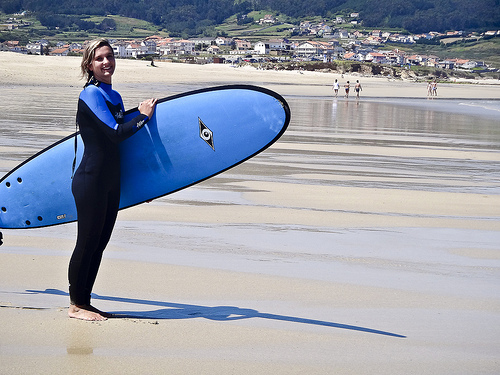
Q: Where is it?
A: This is at the beach.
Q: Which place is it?
A: It is a beach.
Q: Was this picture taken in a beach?
A: Yes, it was taken in a beach.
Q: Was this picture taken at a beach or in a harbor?
A: It was taken at a beach.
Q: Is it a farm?
A: No, it is a beach.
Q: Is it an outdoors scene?
A: Yes, it is outdoors.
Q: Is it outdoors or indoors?
A: It is outdoors.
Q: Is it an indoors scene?
A: No, it is outdoors.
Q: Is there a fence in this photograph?
A: No, there are no fences.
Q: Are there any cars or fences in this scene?
A: No, there are no fences or cars.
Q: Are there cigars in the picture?
A: No, there are no cigars.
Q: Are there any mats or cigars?
A: No, there are no cigars or mats.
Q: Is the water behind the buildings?
A: Yes, the water is behind the buildings.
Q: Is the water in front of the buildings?
A: No, the water is behind the buildings.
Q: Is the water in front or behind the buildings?
A: The water is behind the buildings.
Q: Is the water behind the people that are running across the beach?
A: Yes, the water is behind the people.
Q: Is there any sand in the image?
A: Yes, there is sand.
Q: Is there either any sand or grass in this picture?
A: Yes, there is sand.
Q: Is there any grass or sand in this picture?
A: Yes, there is sand.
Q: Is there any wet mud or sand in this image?
A: Yes, there is wet sand.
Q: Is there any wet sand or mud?
A: Yes, there is wet sand.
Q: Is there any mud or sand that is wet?
A: Yes, the sand is wet.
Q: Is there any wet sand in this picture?
A: Yes, there is wet sand.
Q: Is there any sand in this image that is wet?
A: Yes, there is sand that is wet.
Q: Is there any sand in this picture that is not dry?
A: Yes, there is wet sand.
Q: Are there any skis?
A: No, there are no skis.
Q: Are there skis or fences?
A: No, there are no skis or fences.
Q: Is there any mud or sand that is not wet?
A: No, there is sand but it is wet.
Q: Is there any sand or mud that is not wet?
A: No, there is sand but it is wet.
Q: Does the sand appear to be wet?
A: Yes, the sand is wet.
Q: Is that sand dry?
A: No, the sand is wet.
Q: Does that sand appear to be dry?
A: No, the sand is wet.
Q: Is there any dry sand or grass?
A: No, there is sand but it is wet.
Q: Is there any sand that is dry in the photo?
A: No, there is sand but it is wet.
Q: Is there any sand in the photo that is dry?
A: No, there is sand but it is wet.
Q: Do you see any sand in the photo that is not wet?
A: No, there is sand but it is wet.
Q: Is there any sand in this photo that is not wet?
A: No, there is sand but it is wet.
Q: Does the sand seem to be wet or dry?
A: The sand is wet.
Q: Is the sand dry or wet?
A: The sand is wet.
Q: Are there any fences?
A: No, there are no fences.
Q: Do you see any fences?
A: No, there are no fences.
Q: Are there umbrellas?
A: No, there are no umbrellas.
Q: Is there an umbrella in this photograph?
A: No, there are no umbrellas.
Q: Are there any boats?
A: No, there are no boats.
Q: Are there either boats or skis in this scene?
A: No, there are no boats or skis.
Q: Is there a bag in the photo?
A: No, there are no bags.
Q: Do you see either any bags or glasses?
A: No, there are no bags or glasses.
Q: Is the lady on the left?
A: Yes, the lady is on the left of the image.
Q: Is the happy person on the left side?
A: Yes, the lady is on the left of the image.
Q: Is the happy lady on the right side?
A: No, the lady is on the left of the image.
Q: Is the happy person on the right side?
A: No, the lady is on the left of the image.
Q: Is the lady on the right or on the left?
A: The lady is on the left of the image.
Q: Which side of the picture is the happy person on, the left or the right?
A: The lady is on the left of the image.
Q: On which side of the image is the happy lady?
A: The lady is on the left of the image.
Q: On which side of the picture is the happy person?
A: The lady is on the left of the image.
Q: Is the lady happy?
A: Yes, the lady is happy.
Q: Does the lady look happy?
A: Yes, the lady is happy.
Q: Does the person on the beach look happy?
A: Yes, the lady is happy.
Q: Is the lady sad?
A: No, the lady is happy.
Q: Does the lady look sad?
A: No, the lady is happy.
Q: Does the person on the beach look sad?
A: No, the lady is happy.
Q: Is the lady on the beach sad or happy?
A: The lady is happy.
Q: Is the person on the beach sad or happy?
A: The lady is happy.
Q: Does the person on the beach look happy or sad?
A: The lady is happy.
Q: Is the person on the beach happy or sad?
A: The lady is happy.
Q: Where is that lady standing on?
A: The lady is standing on the beach.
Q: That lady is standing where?
A: The lady is standing on the beach.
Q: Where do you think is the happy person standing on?
A: The lady is standing on the beach.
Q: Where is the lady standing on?
A: The lady is standing on the beach.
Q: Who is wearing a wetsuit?
A: The lady is wearing a wetsuit.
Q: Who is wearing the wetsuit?
A: The lady is wearing a wetsuit.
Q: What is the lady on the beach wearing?
A: The lady is wearing a wetsuit.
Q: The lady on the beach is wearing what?
A: The lady is wearing a wetsuit.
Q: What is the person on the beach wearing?
A: The lady is wearing a wetsuit.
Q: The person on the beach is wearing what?
A: The lady is wearing a wetsuit.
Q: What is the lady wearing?
A: The lady is wearing a wetsuit.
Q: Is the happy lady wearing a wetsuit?
A: Yes, the lady is wearing a wetsuit.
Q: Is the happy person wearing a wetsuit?
A: Yes, the lady is wearing a wetsuit.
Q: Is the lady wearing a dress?
A: No, the lady is wearing a wetsuit.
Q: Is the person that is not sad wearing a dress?
A: No, the lady is wearing a wetsuit.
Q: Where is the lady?
A: The lady is on the beach.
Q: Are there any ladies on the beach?
A: Yes, there is a lady on the beach.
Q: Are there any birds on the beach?
A: No, there is a lady on the beach.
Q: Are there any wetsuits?
A: Yes, there is a wetsuit.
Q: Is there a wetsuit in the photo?
A: Yes, there is a wetsuit.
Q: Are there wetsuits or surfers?
A: Yes, there is a wetsuit.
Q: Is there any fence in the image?
A: No, there are no fences.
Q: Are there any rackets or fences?
A: No, there are no fences or rackets.